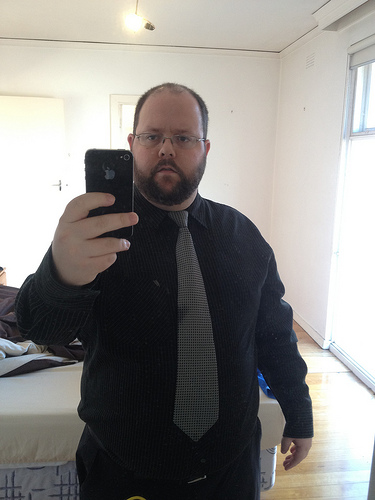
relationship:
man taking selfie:
[17, 79, 320, 495] [33, 84, 225, 268]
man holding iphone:
[17, 79, 320, 495] [83, 146, 135, 242]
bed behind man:
[3, 283, 285, 496] [17, 79, 320, 495]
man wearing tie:
[17, 79, 320, 495] [166, 209, 223, 443]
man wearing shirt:
[17, 79, 320, 495] [12, 189, 315, 484]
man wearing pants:
[17, 79, 320, 495] [77, 423, 262, 497]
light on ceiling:
[119, 9, 164, 42] [3, 6, 334, 58]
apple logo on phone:
[102, 167, 119, 182] [83, 146, 135, 242]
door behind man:
[105, 92, 212, 212] [17, 79, 320, 495]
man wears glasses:
[17, 79, 320, 495] [134, 129, 206, 151]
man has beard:
[17, 79, 320, 495] [130, 143, 208, 206]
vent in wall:
[298, 48, 322, 71] [275, 13, 375, 350]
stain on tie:
[176, 299, 190, 324] [166, 209, 223, 443]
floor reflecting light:
[260, 318, 373, 496] [311, 346, 374, 499]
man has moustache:
[17, 79, 320, 495] [149, 159, 190, 179]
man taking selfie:
[17, 79, 320, 495] [51, 84, 273, 287]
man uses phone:
[17, 79, 320, 495] [81, 143, 142, 247]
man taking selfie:
[17, 79, 320, 495] [71, 120, 214, 243]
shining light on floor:
[312, 364, 374, 499] [260, 318, 373, 496]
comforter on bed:
[1, 277, 81, 371] [3, 283, 285, 496]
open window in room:
[338, 48, 371, 144] [0, 1, 372, 498]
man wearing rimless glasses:
[17, 79, 320, 495] [124, 130, 211, 147]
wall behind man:
[29, 25, 347, 87] [53, 93, 302, 481]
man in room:
[17, 79, 320, 495] [0, 1, 372, 498]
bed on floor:
[3, 283, 285, 496] [255, 305, 373, 499]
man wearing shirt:
[17, 79, 320, 495] [15, 182, 314, 437]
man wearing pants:
[17, 79, 320, 495] [76, 417, 260, 498]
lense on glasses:
[174, 130, 195, 149] [126, 128, 211, 154]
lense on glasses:
[128, 125, 161, 152] [126, 128, 211, 154]